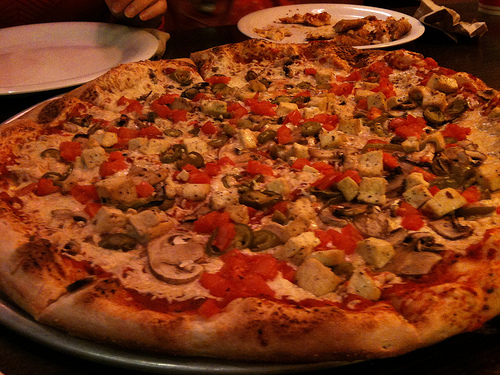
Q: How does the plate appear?
A: Empty.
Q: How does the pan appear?
A: Large.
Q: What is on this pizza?
A: Cheese.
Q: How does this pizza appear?
A: Big.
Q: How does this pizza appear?
A: Very big.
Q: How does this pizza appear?
A: Very big.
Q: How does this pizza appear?
A: Very big.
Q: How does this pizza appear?
A: Very big.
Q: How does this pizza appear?
A: Very big.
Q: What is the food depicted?
A: Pizza.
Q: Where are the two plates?
A: Back of pizza.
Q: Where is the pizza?
A: Silver tray.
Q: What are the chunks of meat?
A: Chicken.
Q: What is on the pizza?
A: Toppings.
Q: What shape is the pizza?
A: Circular.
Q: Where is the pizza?
A: On a pan.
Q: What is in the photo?
A: A person's hand.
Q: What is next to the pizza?
A: Plate.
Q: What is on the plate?
A: Food.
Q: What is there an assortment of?
A: Vegetables.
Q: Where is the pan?
A: On the table.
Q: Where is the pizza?
A: On a pan.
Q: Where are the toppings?
A: On the pizza.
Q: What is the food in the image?
A: Pizza.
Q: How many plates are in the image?
A: Two.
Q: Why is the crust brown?
A: It's been baked.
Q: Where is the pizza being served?
A: At a restaurant.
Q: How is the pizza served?
A: By the slice.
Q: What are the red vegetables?
A: Tomatoes.